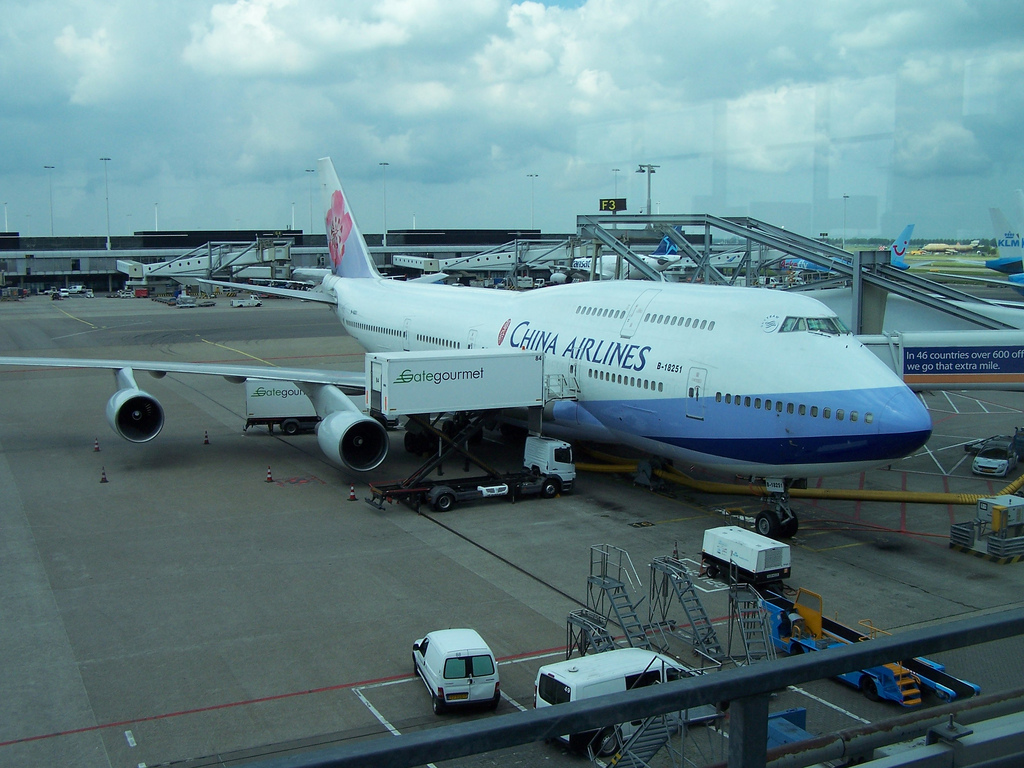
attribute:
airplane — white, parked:
[32, 158, 1022, 481]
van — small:
[397, 607, 506, 702]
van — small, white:
[394, 621, 500, 698]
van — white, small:
[405, 620, 504, 732]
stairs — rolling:
[536, 532, 732, 654]